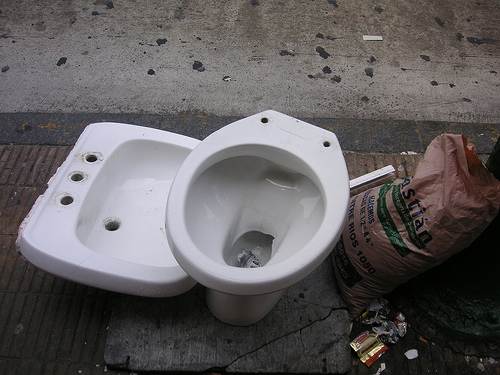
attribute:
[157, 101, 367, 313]
toilet — white, porcelain, missing back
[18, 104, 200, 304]
sink — white, bathroom, porcelain, missing fixtures, disconnected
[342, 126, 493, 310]
brown bag — plastic, mixable cement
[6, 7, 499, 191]
sidewalk — grey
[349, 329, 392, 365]
plastic cover — gold, red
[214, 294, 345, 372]
cement block — crack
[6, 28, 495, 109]
street — gray, black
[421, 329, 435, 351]
electrical wiring — broken